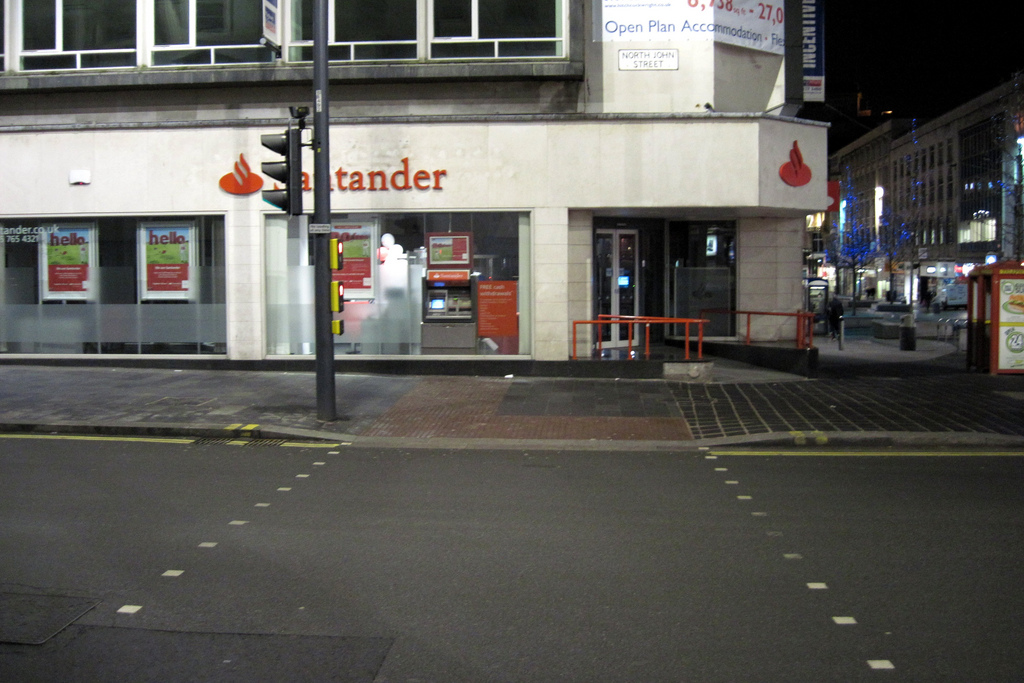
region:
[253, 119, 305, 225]
A stoplight attached to a tall pole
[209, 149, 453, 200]
An orange logo and business name against a white background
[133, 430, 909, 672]
A pedestrian crosswalk with white borders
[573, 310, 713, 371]
Orange handrails attached to a building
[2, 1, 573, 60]
Windows on the second floor of a building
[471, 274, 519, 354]
An orange sign with white letters in the window of a store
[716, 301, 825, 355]
An orange handrail at the entrance to a store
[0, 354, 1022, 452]
A sidewalk made of bricks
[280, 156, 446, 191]
the text is red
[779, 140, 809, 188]
the logo is red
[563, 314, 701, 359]
the bars are red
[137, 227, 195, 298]
sign on the window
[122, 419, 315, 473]
lines by the sidewalk are yellow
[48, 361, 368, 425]
the sidewalk is drak gray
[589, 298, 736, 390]
the rails are red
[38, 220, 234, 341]
signs on the store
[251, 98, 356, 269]
the signal light on post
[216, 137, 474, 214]
the letters are red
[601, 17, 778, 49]
the letters are blue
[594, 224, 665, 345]
doors to the store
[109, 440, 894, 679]
pedestrian walkway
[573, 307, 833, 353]
railing on sides of store entry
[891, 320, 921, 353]
trash can on the sidewalk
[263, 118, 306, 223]
street signal next to crosswalk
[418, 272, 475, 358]
atm machine on side of store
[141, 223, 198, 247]
hello is written on the poster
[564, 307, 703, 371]
railings are red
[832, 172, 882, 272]
lights are blue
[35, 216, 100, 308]
the large sign in the window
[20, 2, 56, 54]
a window on a building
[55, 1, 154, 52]
a window on a building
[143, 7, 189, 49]
a window on a building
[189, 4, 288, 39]
a window on a building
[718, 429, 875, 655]
lines are white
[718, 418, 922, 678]
lines are on road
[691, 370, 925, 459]
the brick is red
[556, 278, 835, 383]
the rails are orange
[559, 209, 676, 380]
a set of glass doors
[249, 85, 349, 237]
a traffic light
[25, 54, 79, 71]
glass window on building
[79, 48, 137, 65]
glass window on building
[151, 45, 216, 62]
glass window on building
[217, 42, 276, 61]
glass window on building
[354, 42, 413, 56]
glass window on building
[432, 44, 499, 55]
glass window on building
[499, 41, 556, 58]
glass window on building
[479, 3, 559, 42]
glass window on building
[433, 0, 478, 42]
glass window on building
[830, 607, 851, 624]
A square in the road.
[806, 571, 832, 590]
A square in the road.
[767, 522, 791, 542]
A square in the road.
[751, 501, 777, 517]
A square in the road.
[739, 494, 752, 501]
A square in the road.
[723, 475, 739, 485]
A square in the road.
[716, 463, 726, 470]
A square in the road.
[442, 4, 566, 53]
A window on a building.